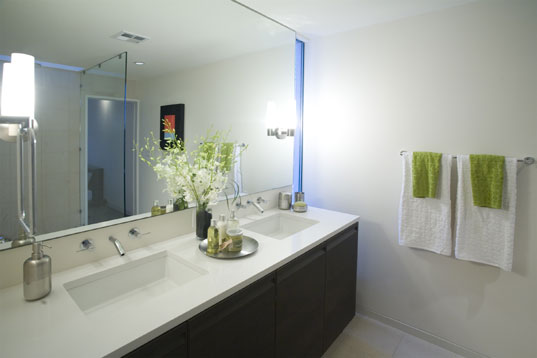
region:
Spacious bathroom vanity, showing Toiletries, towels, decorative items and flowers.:
[1, 0, 528, 353]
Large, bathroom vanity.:
[0, 4, 378, 352]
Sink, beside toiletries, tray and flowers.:
[155, 130, 313, 262]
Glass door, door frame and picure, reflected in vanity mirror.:
[75, 24, 199, 217]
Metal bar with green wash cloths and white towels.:
[370, 68, 533, 286]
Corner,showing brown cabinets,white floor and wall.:
[272, 274, 472, 356]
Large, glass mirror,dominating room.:
[2, 4, 301, 244]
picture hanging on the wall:
[154, 99, 190, 156]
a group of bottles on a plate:
[196, 208, 262, 260]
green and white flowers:
[131, 125, 248, 242]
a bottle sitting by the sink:
[19, 237, 56, 307]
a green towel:
[466, 150, 515, 212]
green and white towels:
[390, 142, 525, 278]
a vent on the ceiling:
[113, 28, 152, 49]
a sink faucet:
[103, 230, 131, 262]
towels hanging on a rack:
[393, 142, 536, 273]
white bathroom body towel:
[454, 150, 519, 271]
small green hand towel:
[469, 153, 505, 209]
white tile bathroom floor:
[324, 312, 462, 355]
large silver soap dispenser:
[21, 238, 51, 301]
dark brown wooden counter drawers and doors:
[123, 222, 357, 357]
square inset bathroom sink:
[63, 248, 208, 325]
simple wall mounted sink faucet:
[75, 224, 151, 257]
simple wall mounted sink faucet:
[232, 194, 266, 213]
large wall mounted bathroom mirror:
[0, 0, 306, 253]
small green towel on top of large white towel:
[397, 148, 453, 258]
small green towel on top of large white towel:
[454, 152, 518, 273]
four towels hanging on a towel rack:
[397, 147, 535, 272]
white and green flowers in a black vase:
[129, 117, 250, 240]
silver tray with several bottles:
[196, 209, 260, 260]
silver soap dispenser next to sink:
[22, 225, 212, 317]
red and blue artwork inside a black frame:
[157, 102, 185, 154]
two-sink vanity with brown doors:
[1, 183, 360, 356]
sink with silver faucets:
[60, 224, 212, 317]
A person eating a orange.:
[286, 213, 353, 285]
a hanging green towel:
[409, 148, 444, 202]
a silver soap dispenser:
[20, 240, 52, 302]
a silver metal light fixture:
[273, 92, 299, 141]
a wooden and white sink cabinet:
[1, 180, 363, 355]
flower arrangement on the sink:
[161, 149, 220, 235]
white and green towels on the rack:
[408, 149, 508, 270]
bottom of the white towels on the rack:
[399, 200, 519, 261]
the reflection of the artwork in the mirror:
[153, 101, 189, 155]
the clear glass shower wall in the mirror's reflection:
[84, 59, 128, 240]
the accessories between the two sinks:
[203, 218, 245, 252]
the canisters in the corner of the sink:
[282, 192, 304, 213]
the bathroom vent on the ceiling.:
[114, 26, 151, 52]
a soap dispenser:
[24, 238, 55, 303]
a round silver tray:
[197, 233, 259, 257]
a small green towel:
[411, 149, 441, 203]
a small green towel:
[468, 151, 507, 208]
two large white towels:
[397, 151, 518, 272]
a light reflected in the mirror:
[96, 96, 113, 112]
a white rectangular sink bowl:
[64, 242, 204, 319]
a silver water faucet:
[106, 235, 126, 257]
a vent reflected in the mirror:
[110, 27, 146, 46]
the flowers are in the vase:
[141, 134, 236, 234]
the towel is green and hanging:
[412, 150, 441, 198]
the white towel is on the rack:
[398, 147, 458, 265]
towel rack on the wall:
[397, 145, 534, 171]